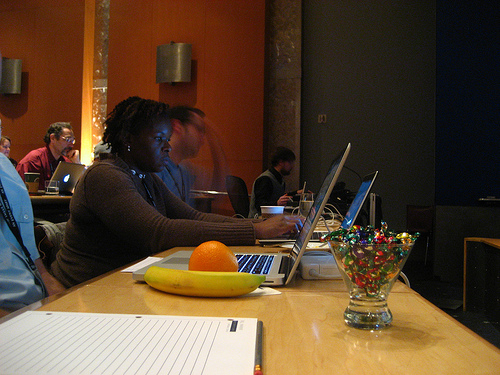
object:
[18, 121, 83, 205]
people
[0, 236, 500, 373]
table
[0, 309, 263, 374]
paper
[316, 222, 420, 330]
glass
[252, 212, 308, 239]
hands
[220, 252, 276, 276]
keyboard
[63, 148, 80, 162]
hand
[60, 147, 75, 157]
chin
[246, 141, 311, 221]
man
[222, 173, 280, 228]
chair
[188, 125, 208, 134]
glasses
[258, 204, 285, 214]
top of cup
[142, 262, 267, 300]
banana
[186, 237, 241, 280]
orange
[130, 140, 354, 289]
computers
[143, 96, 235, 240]
man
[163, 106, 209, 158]
head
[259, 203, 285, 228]
coffee cup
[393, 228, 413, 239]
candy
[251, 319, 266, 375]
pencil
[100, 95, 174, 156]
hair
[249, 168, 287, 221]
vest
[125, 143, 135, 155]
earring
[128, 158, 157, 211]
lanyard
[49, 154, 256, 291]
shirt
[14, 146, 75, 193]
shirt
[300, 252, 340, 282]
charger